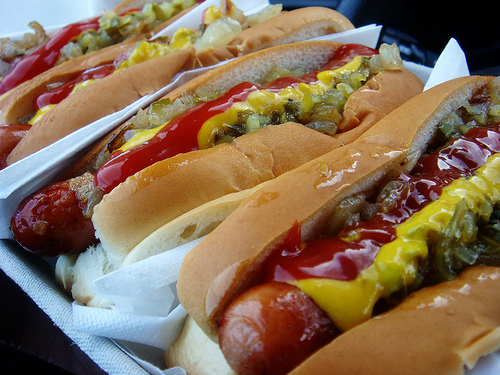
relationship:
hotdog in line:
[219, 281, 336, 375] [31, 76, 273, 323]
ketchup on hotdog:
[155, 127, 206, 158] [9, 150, 177, 256]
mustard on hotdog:
[291, 82, 318, 109] [9, 150, 177, 256]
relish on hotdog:
[319, 100, 347, 123] [9, 150, 177, 256]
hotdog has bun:
[9, 150, 177, 256] [120, 170, 208, 240]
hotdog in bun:
[9, 150, 177, 256] [120, 170, 208, 240]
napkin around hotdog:
[87, 263, 185, 355] [9, 150, 177, 256]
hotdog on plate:
[219, 281, 336, 375] [4, 268, 116, 371]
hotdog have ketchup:
[219, 281, 336, 375] [155, 127, 206, 158]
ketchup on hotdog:
[312, 249, 353, 271] [226, 219, 398, 366]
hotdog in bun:
[219, 281, 336, 375] [93, 65, 425, 273]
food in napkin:
[303, 37, 466, 286] [0, 25, 382, 240]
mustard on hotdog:
[332, 286, 369, 322] [226, 219, 398, 366]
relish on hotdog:
[439, 229, 487, 271] [226, 219, 398, 366]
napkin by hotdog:
[21, 125, 105, 166] [9, 150, 177, 256]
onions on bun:
[200, 24, 243, 49] [244, 12, 320, 70]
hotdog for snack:
[219, 281, 336, 375] [206, 69, 349, 203]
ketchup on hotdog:
[165, 121, 199, 152] [219, 281, 336, 375]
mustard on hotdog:
[291, 82, 318, 100] [219, 281, 336, 375]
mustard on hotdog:
[369, 256, 410, 294] [219, 281, 336, 375]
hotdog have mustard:
[219, 281, 336, 375] [291, 82, 318, 100]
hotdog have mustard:
[219, 281, 336, 375] [369, 256, 410, 294]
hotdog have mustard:
[9, 175, 102, 257] [291, 82, 318, 100]